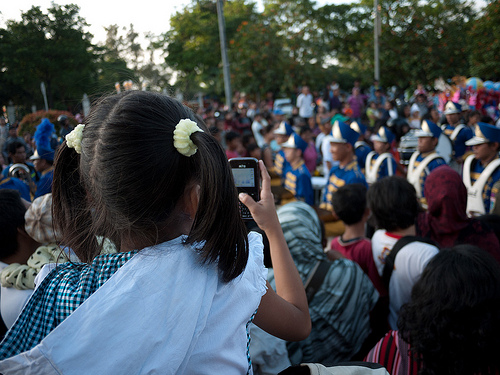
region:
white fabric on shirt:
[61, 355, 78, 357]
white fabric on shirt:
[101, 362, 118, 368]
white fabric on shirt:
[140, 355, 157, 359]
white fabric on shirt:
[170, 333, 178, 340]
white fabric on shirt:
[119, 313, 136, 329]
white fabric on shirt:
[160, 263, 174, 271]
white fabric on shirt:
[219, 323, 225, 325]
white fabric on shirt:
[202, 350, 223, 363]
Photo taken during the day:
[16, 10, 491, 370]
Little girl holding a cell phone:
[45, 91, 317, 365]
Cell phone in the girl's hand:
[222, 155, 279, 224]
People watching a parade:
[9, 85, 494, 367]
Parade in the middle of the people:
[7, 97, 498, 260]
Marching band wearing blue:
[0, 123, 494, 220]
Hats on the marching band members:
[5, 114, 492, 149]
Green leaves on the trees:
[21, 15, 477, 81]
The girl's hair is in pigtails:
[35, 100, 252, 253]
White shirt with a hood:
[0, 255, 261, 369]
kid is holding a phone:
[57, 59, 288, 356]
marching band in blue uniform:
[235, 74, 499, 224]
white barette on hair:
[157, 118, 203, 145]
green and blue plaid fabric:
[47, 276, 84, 296]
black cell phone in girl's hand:
[217, 152, 270, 224]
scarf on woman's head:
[261, 193, 336, 280]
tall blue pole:
[203, 14, 253, 108]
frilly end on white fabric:
[235, 316, 260, 348]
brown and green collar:
[333, 228, 365, 249]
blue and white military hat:
[316, 114, 363, 150]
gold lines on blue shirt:
[318, 169, 355, 208]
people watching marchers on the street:
[281, 100, 462, 235]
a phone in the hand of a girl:
[228, 153, 260, 230]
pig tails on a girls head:
[40, 86, 252, 285]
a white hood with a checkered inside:
[3, 229, 211, 373]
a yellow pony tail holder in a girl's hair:
[172, 111, 202, 158]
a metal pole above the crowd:
[205, 0, 235, 110]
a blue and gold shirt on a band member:
[315, 157, 361, 212]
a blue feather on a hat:
[31, 117, 51, 152]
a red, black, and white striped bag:
[360, 330, 415, 370]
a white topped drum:
[307, 170, 323, 202]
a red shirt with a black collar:
[324, 232, 383, 285]